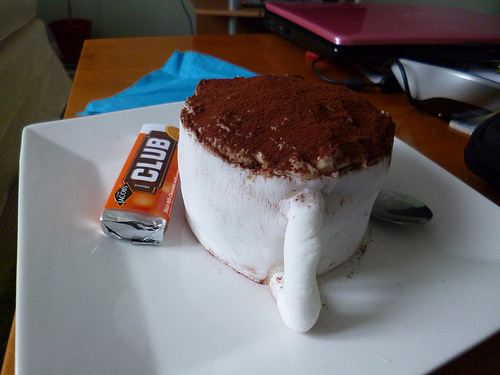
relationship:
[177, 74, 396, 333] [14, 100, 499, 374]
dessert on plate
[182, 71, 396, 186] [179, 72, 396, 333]
chocolate powder on dessert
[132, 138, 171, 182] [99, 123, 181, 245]
club on bar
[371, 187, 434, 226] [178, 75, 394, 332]
spoon near cup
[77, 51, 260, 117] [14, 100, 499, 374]
napkin next to plate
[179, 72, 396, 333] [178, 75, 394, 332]
dessert shaped like a cup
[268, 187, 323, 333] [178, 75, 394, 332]
handle on cup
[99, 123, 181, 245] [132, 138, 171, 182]
bar says club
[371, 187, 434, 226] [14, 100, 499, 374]
spoon on plate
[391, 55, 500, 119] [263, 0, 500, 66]
mouse near laptop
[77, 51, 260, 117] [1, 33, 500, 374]
napkin on table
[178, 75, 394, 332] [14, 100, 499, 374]
cup on plate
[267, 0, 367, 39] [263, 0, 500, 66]
shadow on laptop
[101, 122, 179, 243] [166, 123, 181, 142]
chocolate bar flavored orange